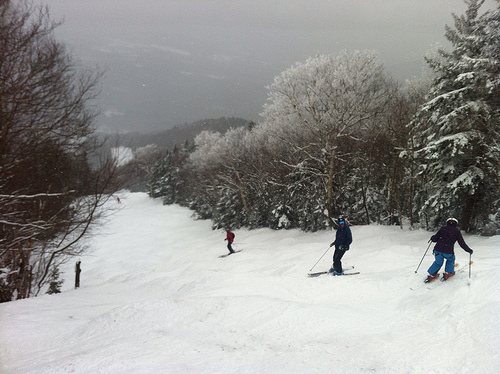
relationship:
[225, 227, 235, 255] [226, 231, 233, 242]
people wearing coat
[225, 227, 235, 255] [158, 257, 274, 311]
people skiing down slope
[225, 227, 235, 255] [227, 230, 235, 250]
people wearing snowsuit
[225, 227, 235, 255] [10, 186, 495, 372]
people skiing down slope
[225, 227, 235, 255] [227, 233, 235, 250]
people wearing snow suit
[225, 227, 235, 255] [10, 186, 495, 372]
people going down slope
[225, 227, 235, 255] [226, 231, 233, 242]
people in coat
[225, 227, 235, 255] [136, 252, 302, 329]
people going down slope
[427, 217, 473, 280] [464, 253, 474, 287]
people holding pole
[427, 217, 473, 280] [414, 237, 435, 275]
people holding pole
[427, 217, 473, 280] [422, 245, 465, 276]
people wearing ski pants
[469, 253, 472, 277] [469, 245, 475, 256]
pole held by hand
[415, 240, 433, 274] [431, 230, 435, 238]
pole held by hand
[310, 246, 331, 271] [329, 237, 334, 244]
poles held by hand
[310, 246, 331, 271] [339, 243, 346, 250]
poles held by hand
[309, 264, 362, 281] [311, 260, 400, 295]
skis are on feet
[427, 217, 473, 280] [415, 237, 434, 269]
people holding poles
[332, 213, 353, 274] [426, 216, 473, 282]
people are skiing people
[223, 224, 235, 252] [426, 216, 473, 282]
people are skiing people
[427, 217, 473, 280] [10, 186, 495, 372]
people are traveling down slope